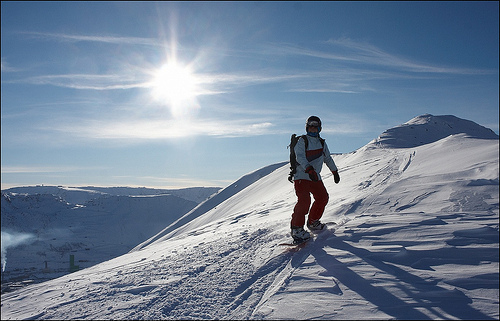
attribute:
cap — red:
[305, 110, 323, 128]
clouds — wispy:
[286, 39, 461, 101]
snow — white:
[181, 252, 349, 291]